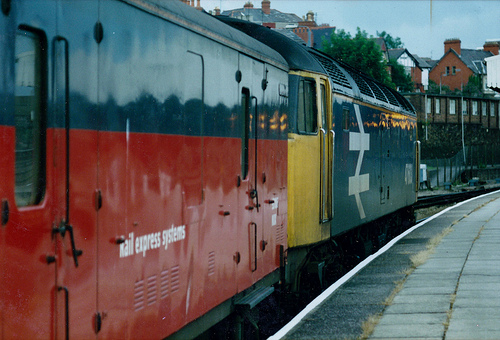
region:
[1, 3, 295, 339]
red and black train on tracks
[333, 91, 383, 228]
white painted design on train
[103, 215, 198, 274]
white words on red train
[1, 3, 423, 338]
two train cars on track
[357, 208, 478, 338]
dead grass growning between paving stones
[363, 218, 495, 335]
grey paving stones in path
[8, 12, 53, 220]
window in red and black train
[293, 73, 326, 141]
window in yellow and black train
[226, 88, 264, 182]
window in red black train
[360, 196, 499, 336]
yellow safety guide on the train station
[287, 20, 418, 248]
a yellow and gray train engine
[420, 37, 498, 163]
a house on the hill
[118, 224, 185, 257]
a name brand logo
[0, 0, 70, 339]
the train engine access door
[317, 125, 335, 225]
hand rail to the access door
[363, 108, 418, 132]
a reflection on the side of the train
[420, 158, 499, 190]
a fence running along the train tracks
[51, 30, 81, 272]
a hand rail near the access door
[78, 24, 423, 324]
train parked in the railway station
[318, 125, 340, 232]
silver handle of the train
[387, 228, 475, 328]
platform at the railway station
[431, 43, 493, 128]
buildings near the railway station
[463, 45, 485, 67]
roof of the building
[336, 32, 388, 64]
trees behind the train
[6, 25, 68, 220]
window of the train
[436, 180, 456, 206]
train track made with metal rod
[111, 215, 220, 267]
name of locomotive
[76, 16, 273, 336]
red and blue color coated carrier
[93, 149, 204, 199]
side of red train car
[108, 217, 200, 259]
Mail express sign on train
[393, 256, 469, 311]
stone pavement blocks near train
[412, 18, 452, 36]
Beautiful blue sky in distance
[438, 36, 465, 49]
Chimney of nearby house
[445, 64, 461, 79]
Upstairs window of nearby house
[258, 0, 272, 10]
Chimney of nearby house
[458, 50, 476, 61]
Part of gray house roof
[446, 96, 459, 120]
Window of nearby house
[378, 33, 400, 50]
Part of green nearby trees